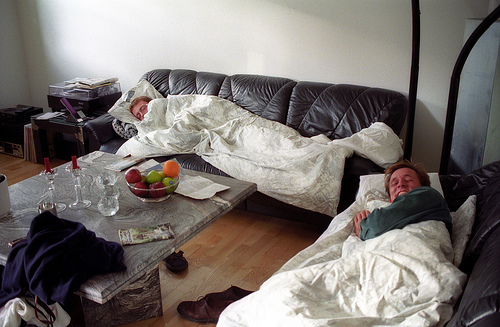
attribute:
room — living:
[3, 2, 499, 326]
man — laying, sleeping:
[128, 97, 342, 157]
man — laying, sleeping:
[352, 159, 453, 326]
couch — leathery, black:
[81, 68, 406, 216]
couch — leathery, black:
[439, 160, 500, 327]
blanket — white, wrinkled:
[115, 94, 406, 216]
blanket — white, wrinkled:
[216, 220, 468, 326]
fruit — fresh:
[124, 160, 180, 196]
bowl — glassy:
[124, 183, 179, 204]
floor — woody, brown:
[1, 153, 329, 327]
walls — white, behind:
[1, 0, 499, 171]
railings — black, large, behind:
[402, 1, 421, 167]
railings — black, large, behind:
[439, 6, 498, 167]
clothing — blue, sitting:
[0, 211, 127, 307]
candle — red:
[41, 156, 54, 173]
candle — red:
[70, 154, 82, 169]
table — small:
[34, 112, 113, 164]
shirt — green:
[359, 185, 453, 242]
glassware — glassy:
[96, 170, 121, 217]